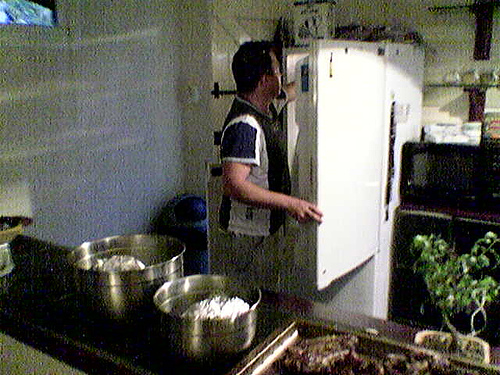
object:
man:
[218, 38, 323, 292]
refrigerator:
[286, 38, 425, 320]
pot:
[153, 273, 262, 356]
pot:
[65, 232, 186, 322]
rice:
[179, 295, 250, 321]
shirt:
[218, 87, 291, 238]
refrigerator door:
[307, 39, 379, 292]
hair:
[231, 39, 275, 97]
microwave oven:
[400, 141, 500, 215]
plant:
[408, 230, 500, 364]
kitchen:
[0, 0, 500, 375]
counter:
[397, 202, 499, 229]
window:
[0, 0, 60, 29]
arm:
[274, 81, 299, 114]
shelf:
[427, 0, 499, 61]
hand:
[287, 197, 322, 225]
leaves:
[407, 230, 499, 315]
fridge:
[283, 38, 424, 321]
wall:
[0, 0, 186, 219]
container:
[0, 242, 16, 279]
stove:
[29, 245, 273, 374]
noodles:
[181, 294, 250, 322]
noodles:
[93, 254, 147, 272]